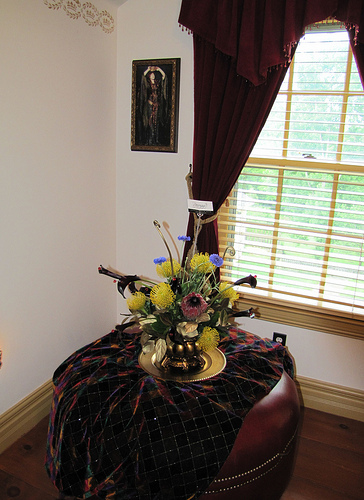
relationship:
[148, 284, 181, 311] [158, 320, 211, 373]
flower in vase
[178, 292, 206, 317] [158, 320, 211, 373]
flower in vase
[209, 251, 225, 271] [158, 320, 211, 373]
flower on vase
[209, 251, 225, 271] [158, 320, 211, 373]
flower in vase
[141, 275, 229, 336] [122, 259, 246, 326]
greenery on flowers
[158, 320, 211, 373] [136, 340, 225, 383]
vase on plate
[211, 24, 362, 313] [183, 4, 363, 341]
blinds on window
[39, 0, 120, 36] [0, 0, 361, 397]
design on wall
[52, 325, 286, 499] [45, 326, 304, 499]
blanket over cushion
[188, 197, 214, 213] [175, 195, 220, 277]
card on stand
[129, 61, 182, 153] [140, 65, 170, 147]
picture of woman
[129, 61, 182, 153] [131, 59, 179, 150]
picture in brown frame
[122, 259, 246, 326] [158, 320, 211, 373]
flowers in vase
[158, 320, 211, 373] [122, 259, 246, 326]
vase with flowers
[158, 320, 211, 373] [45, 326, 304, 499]
vase on cushion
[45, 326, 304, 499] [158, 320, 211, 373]
cushion under vase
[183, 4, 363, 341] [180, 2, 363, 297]
window with curtains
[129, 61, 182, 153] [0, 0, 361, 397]
picture on wall